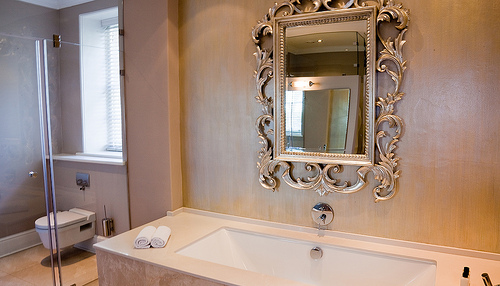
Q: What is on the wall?
A: Mirror.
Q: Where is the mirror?
A: On the wall.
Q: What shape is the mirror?
A: It is rectangular.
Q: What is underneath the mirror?
A: The white tub.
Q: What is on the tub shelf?
A: Two towels.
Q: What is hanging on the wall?
A: The mirror.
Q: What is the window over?
A: The toilet.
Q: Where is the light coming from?
A: The window.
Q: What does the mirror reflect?
A: The window and door.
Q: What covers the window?
A: The shutter.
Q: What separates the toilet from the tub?
A: A clear door.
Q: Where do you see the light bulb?
A: From the reflection in the mirror.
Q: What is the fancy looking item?
A: Mirror.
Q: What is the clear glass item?
A: Door.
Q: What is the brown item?
A: Wall.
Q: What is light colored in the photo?
A: Counter.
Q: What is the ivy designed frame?
A: Bathroom wall mirror.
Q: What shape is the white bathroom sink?
A: Rectangular.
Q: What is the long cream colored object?
A: Bathroom vanity.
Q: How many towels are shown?
A: Two.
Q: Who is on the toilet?
A: No one.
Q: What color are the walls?
A: Tan.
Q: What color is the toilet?
A: White.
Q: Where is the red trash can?
A: No trash can.